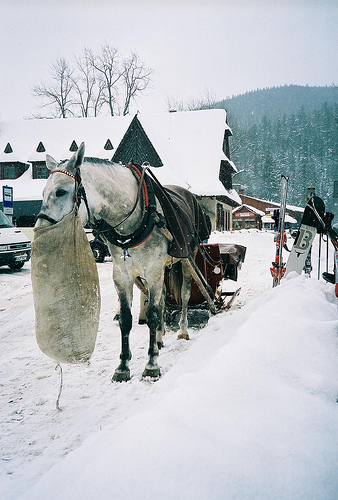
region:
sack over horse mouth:
[33, 212, 103, 370]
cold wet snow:
[141, 426, 272, 495]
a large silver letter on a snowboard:
[290, 225, 312, 258]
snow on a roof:
[178, 107, 218, 160]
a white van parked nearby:
[0, 212, 28, 268]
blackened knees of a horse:
[113, 305, 160, 377]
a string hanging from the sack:
[44, 361, 67, 411]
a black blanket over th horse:
[154, 182, 206, 255]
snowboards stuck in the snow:
[264, 166, 318, 281]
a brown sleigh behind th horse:
[176, 235, 256, 341]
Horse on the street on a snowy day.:
[0, 138, 261, 492]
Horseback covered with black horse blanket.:
[143, 175, 216, 255]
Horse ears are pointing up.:
[41, 140, 89, 169]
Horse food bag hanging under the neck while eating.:
[26, 197, 100, 363]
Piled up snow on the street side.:
[176, 342, 333, 496]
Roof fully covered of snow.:
[0, 108, 226, 158]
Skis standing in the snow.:
[269, 173, 334, 292]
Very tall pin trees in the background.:
[247, 103, 334, 207]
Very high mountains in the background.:
[229, 79, 337, 127]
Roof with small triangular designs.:
[1, 139, 118, 154]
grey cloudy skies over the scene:
[239, 32, 276, 62]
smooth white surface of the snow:
[209, 416, 319, 499]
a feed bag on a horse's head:
[24, 186, 110, 368]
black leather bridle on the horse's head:
[36, 176, 89, 227]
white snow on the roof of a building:
[176, 118, 230, 180]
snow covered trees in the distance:
[229, 88, 332, 201]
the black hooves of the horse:
[108, 361, 162, 387]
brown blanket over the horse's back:
[144, 172, 213, 260]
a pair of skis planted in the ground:
[269, 172, 293, 290]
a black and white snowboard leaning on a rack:
[293, 183, 321, 281]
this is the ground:
[227, 344, 300, 400]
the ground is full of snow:
[181, 431, 270, 466]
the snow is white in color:
[195, 424, 255, 466]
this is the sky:
[194, 13, 258, 48]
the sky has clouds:
[239, 21, 288, 59]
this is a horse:
[20, 141, 256, 381]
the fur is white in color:
[92, 173, 123, 201]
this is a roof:
[172, 128, 195, 157]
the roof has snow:
[160, 132, 202, 162]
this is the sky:
[178, 16, 226, 52]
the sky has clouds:
[183, 16, 271, 67]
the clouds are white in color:
[201, 15, 313, 56]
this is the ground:
[229, 306, 289, 375]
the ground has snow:
[172, 392, 253, 436]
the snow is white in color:
[171, 413, 268, 486]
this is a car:
[0, 206, 32, 259]